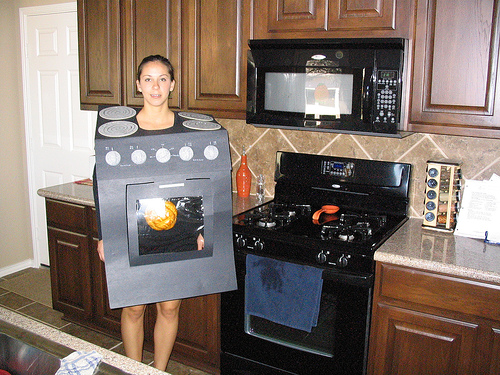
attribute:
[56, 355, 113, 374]
rag — blue, white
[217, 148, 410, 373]
oven — black 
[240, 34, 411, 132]
microwave — black 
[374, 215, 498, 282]
granite countertops — tan 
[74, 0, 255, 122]
cabinets — wood, brown, wooden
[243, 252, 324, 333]
towel — blue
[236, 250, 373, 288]
rack — black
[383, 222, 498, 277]
countertop — granite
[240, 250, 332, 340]
towel — blue 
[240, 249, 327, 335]
towel — blue 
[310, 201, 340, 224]
spoon — orange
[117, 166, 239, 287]
door — panel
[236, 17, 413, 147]
microwave — black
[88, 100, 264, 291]
costume — range 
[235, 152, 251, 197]
bottle — orange 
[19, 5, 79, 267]
door — white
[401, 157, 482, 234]
rack — spice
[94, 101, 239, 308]
stove — grey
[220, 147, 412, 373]
stove — black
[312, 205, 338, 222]
spoon rest — red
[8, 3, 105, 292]
door — wood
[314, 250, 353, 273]
handle — black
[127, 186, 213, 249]
panel — clear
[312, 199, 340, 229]
spoon — orange